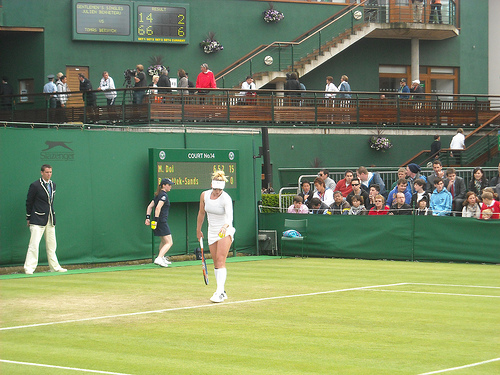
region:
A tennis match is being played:
[0, 0, 498, 373]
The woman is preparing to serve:
[193, 169, 237, 305]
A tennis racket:
[197, 234, 210, 289]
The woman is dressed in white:
[194, 165, 236, 302]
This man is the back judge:
[21, 162, 68, 275]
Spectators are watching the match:
[286, 159, 498, 219]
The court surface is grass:
[1, 254, 498, 374]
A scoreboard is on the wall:
[69, 0, 191, 46]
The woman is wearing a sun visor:
[209, 168, 229, 191]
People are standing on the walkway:
[40, 60, 429, 122]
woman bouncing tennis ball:
[185, 170, 254, 308]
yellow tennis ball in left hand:
[216, 220, 233, 250]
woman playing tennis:
[184, 147, 261, 304]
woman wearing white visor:
[182, 155, 249, 315]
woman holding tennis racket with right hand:
[193, 170, 247, 312]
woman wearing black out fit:
[140, 173, 181, 239]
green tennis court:
[259, 324, 376, 363]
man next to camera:
[117, 56, 152, 109]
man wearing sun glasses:
[345, 175, 365, 194]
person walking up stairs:
[442, 127, 473, 169]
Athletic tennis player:
[193, 167, 237, 307]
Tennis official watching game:
[23, 160, 71, 278]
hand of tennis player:
[223, 236, 232, 258]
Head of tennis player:
[208, 167, 230, 194]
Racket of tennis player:
[198, 248, 210, 294]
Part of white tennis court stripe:
[251, 284, 334, 311]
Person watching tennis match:
[193, 60, 218, 98]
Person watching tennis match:
[286, 195, 310, 214]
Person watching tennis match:
[424, 177, 452, 216]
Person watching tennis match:
[368, 192, 391, 212]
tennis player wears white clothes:
[188, 156, 241, 314]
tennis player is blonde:
[190, 168, 238, 304]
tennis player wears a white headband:
[189, 167, 241, 224]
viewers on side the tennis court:
[285, 152, 495, 222]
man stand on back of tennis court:
[18, 155, 73, 282]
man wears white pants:
[16, 163, 71, 280]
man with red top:
[189, 60, 221, 101]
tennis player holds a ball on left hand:
[190, 165, 242, 305]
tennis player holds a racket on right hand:
[185, 165, 245, 308]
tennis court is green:
[10, 234, 497, 368]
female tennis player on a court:
[192, 170, 237, 301]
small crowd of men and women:
[285, 160, 495, 220]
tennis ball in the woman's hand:
[216, 227, 222, 237]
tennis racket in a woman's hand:
[195, 227, 206, 282]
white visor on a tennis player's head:
[210, 175, 225, 186]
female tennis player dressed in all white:
[194, 169, 237, 304]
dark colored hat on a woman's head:
[157, 176, 178, 185]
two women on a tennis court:
[143, 168, 238, 303]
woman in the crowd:
[368, 195, 388, 213]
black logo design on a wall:
[36, 137, 78, 160]